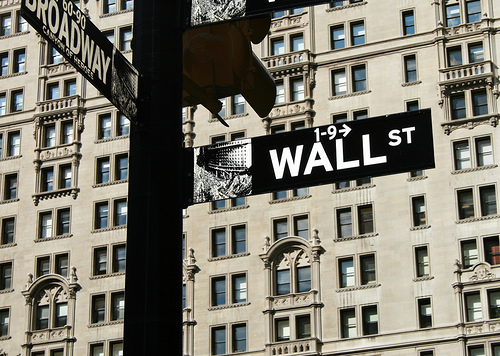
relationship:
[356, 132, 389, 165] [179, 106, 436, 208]
letter on sign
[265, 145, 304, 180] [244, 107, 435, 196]
letter on sign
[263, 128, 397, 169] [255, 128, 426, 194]
letter on sign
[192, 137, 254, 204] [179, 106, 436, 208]
logo on sign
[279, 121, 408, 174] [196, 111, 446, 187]
letter on sign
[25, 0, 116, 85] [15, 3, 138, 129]
lettering on street sign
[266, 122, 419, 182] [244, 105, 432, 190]
wall street on sign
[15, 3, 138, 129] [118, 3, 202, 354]
street sign on pole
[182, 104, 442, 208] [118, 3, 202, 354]
street sign on pole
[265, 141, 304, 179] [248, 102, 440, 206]
letter on sign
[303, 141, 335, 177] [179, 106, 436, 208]
letter on sign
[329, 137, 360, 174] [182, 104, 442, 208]
letter on street sign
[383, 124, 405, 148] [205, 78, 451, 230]
letter on sign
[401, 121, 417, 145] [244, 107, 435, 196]
letter on sign